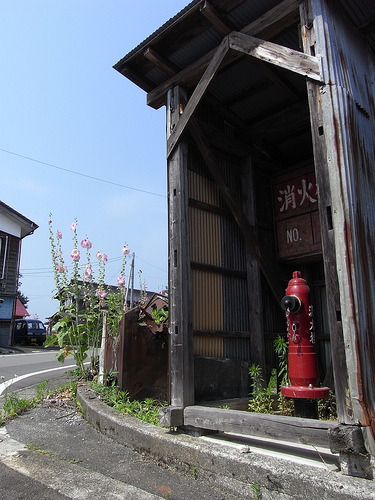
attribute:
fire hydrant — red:
[279, 270, 331, 417]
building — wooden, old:
[112, 1, 372, 478]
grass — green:
[86, 379, 161, 424]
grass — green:
[0, 385, 51, 427]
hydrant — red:
[277, 269, 326, 416]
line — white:
[1, 429, 163, 498]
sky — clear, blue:
[14, 18, 109, 196]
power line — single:
[0, 147, 175, 200]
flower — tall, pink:
[115, 274, 125, 284]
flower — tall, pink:
[121, 246, 130, 255]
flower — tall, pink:
[93, 288, 104, 297]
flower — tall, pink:
[94, 250, 106, 262]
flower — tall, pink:
[79, 238, 91, 250]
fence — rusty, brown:
[115, 311, 170, 401]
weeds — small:
[219, 334, 336, 419]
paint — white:
[16, 371, 33, 381]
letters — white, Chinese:
[273, 176, 320, 216]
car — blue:
[8, 316, 50, 344]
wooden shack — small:
[112, 0, 373, 469]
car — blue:
[11, 317, 46, 344]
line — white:
[0, 359, 93, 393]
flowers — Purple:
[48, 213, 148, 309]